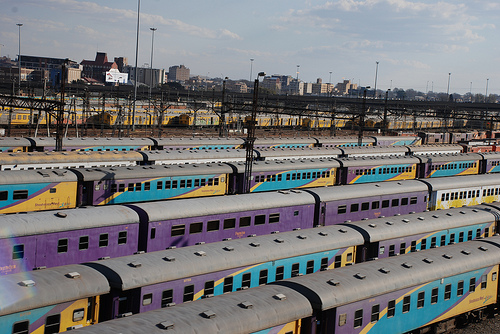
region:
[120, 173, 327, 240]
This is a train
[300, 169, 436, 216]
This is a train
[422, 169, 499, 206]
This is a train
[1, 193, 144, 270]
This is a train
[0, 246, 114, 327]
This is a train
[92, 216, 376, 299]
This is a train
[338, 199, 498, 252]
This is a train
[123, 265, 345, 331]
This is a train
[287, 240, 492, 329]
This is a train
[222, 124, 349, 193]
This is a train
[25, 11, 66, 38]
white clouds in blue sky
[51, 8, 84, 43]
white clouds in blue sky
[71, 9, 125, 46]
white clouds in blue sky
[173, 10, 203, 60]
white clouds in blue sky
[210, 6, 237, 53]
white clouds in blue sky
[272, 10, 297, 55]
white clouds in blue sky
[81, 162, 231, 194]
purple gold and blue train car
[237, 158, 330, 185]
purple gold and blue train car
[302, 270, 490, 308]
purple gold and blue train car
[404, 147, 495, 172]
purple gold and blue train car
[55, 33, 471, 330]
trains on the trakcs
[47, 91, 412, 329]
passenger trains on the tracks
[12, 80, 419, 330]
trains next to each other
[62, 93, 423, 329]
passenger trains next to each other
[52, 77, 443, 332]
trains outside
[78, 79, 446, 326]
passenger trains that are outside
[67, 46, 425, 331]
tracks with trains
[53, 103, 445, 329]
tracks with passenger train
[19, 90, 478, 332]
an area with trains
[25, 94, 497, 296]
an area with passenger train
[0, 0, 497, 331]
Multiple train coaches on tracks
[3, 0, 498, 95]
A sparsely clouded sky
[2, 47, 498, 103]
The city's metropolis in the background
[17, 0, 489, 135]
The scattered city lighting post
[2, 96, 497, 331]
The multiple colored coaches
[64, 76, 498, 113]
A horizontal bridge across the station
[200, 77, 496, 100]
The sparsely grown trees in the background horizon with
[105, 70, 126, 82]
A white billboard next to the buildings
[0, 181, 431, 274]
The three coaches colored purple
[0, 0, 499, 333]
A bright day in a railway station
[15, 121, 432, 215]
blue and yellow trains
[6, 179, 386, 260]
grey and purple trains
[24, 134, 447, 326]
grey roofs on trains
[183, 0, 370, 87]
sky is blue with clouds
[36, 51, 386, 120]
tall buildings in background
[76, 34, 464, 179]
black power lines over trains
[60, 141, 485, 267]
rectangular windows on trains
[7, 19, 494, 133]
light poles in background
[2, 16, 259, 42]
layered clouds in sky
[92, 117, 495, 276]
blue stripes on trains